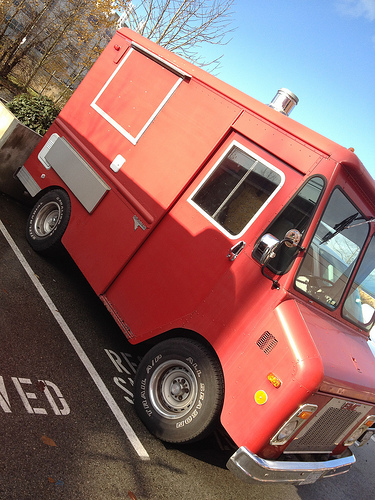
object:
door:
[103, 126, 305, 338]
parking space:
[0, 204, 150, 498]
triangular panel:
[251, 174, 328, 276]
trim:
[89, 103, 136, 147]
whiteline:
[0, 219, 151, 462]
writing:
[0, 374, 71, 415]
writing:
[104, 348, 136, 404]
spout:
[268, 87, 299, 116]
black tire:
[26, 189, 72, 253]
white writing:
[56, 196, 63, 224]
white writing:
[29, 202, 43, 240]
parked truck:
[16, 27, 374, 487]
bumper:
[225, 447, 356, 487]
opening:
[89, 41, 192, 146]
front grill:
[297, 406, 362, 446]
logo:
[341, 401, 361, 411]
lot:
[0, 248, 91, 498]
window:
[186, 139, 285, 240]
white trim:
[90, 40, 192, 147]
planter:
[0, 97, 44, 194]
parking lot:
[0, 26, 375, 500]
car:
[299, 230, 363, 324]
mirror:
[251, 233, 280, 265]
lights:
[254, 372, 283, 406]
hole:
[256, 330, 278, 355]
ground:
[0, 242, 162, 500]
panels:
[104, 130, 305, 335]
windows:
[252, 173, 375, 331]